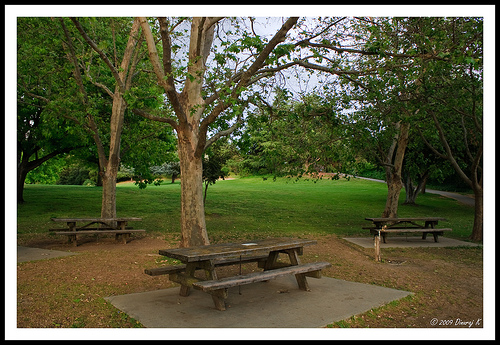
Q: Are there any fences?
A: No, there are no fences.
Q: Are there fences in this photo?
A: No, there are no fences.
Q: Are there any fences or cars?
A: No, there are no fences or cars.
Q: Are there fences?
A: No, there are no fences.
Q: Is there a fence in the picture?
A: No, there are no fences.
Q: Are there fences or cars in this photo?
A: No, there are no fences or cars.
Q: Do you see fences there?
A: No, there are no fences.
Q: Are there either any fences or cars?
A: No, there are no fences or cars.